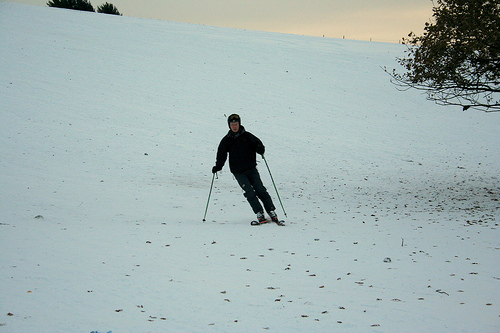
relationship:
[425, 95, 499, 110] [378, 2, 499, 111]
branches of tree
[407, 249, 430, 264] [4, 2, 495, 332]
debris on snow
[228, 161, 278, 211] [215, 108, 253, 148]
pants on person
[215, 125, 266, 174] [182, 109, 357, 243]
coat on person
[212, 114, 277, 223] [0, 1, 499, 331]
man on hill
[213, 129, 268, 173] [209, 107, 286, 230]
coat on man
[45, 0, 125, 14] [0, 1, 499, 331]
trees behind hill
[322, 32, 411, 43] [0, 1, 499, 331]
fence on hill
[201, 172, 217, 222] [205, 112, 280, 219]
pole with man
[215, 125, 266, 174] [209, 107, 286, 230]
coat on man